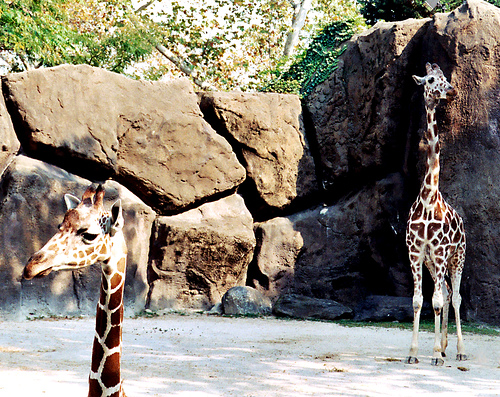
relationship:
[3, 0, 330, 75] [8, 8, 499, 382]
trees behind enclosure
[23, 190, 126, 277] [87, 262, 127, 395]
head and neck